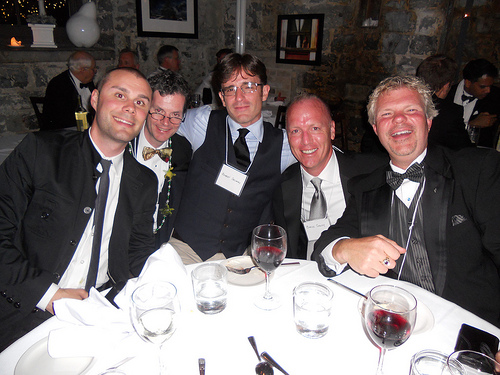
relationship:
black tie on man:
[85, 157, 113, 295] [0, 68, 158, 350]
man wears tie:
[270, 87, 390, 261] [298, 172, 333, 222]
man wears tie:
[266, 94, 378, 240] [305, 172, 324, 224]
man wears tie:
[167, 53, 300, 265] [230, 127, 250, 162]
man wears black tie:
[3, 68, 156, 309] [84, 158, 113, 292]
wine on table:
[250, 220, 289, 311] [0, 247, 498, 373]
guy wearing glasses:
[124, 82, 194, 246] [142, 102, 187, 129]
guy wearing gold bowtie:
[455, 52, 497, 150] [137, 140, 174, 165]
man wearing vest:
[167, 53, 300, 265] [171, 116, 289, 260]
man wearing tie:
[167, 53, 300, 265] [229, 128, 251, 178]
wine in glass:
[252, 246, 284, 272] [245, 220, 288, 306]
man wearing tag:
[167, 53, 300, 265] [214, 160, 246, 195]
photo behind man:
[273, 12, 323, 64] [0, 68, 164, 341]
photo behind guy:
[273, 12, 323, 64] [129, 69, 195, 246]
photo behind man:
[273, 12, 323, 64] [175, 49, 303, 259]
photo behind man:
[273, 12, 323, 64] [251, 96, 376, 263]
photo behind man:
[273, 12, 323, 64] [321, 75, 499, 326]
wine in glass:
[365, 310, 415, 349] [362, 283, 416, 373]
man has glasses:
[167, 53, 300, 265] [220, 80, 263, 97]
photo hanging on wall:
[275, 12, 322, 67] [240, 0, 484, 130]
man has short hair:
[321, 75, 499, 326] [363, 73, 440, 122]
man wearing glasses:
[205, 63, 283, 210] [202, 66, 293, 101]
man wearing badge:
[167, 53, 300, 265] [207, 159, 252, 196]